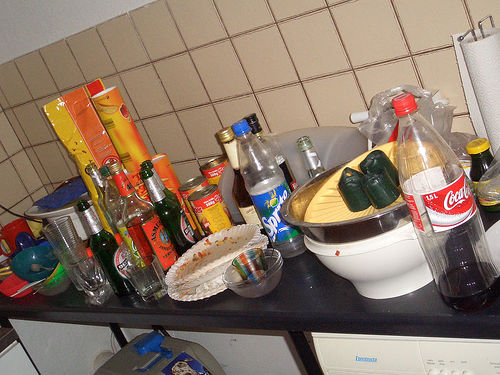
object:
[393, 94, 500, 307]
bottle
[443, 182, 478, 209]
coca-cola